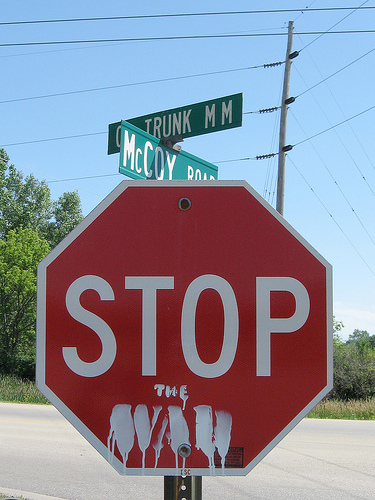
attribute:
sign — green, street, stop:
[101, 109, 243, 166]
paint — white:
[101, 377, 240, 469]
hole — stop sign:
[177, 482, 189, 491]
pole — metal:
[162, 474, 202, 498]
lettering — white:
[139, 109, 192, 138]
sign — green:
[105, 89, 246, 159]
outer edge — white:
[35, 178, 333, 476]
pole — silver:
[277, 86, 288, 117]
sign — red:
[113, 315, 222, 447]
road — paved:
[4, 400, 361, 493]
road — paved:
[4, 405, 349, 497]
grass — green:
[1, 371, 361, 405]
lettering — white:
[63, 273, 309, 377]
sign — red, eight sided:
[36, 180, 334, 477]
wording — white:
[108, 384, 233, 459]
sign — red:
[128, 237, 285, 452]